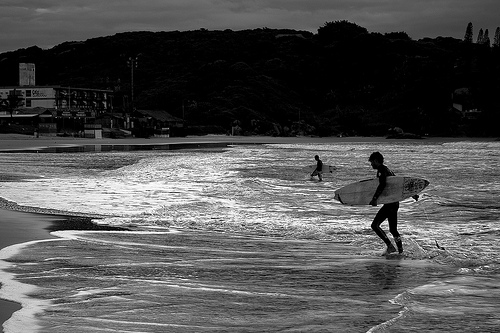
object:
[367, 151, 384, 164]
hair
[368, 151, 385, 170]
head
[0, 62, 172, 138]
building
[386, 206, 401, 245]
leg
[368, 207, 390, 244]
leg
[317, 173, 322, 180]
leg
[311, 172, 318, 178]
leg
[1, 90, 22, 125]
tree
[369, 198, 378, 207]
hand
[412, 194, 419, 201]
hand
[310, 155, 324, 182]
people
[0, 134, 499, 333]
beach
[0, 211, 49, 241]
sand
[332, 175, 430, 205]
people_surfing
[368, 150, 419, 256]
man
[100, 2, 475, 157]
trees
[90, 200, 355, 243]
waves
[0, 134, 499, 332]
water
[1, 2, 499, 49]
sky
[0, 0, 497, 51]
clouds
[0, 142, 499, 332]
ripples